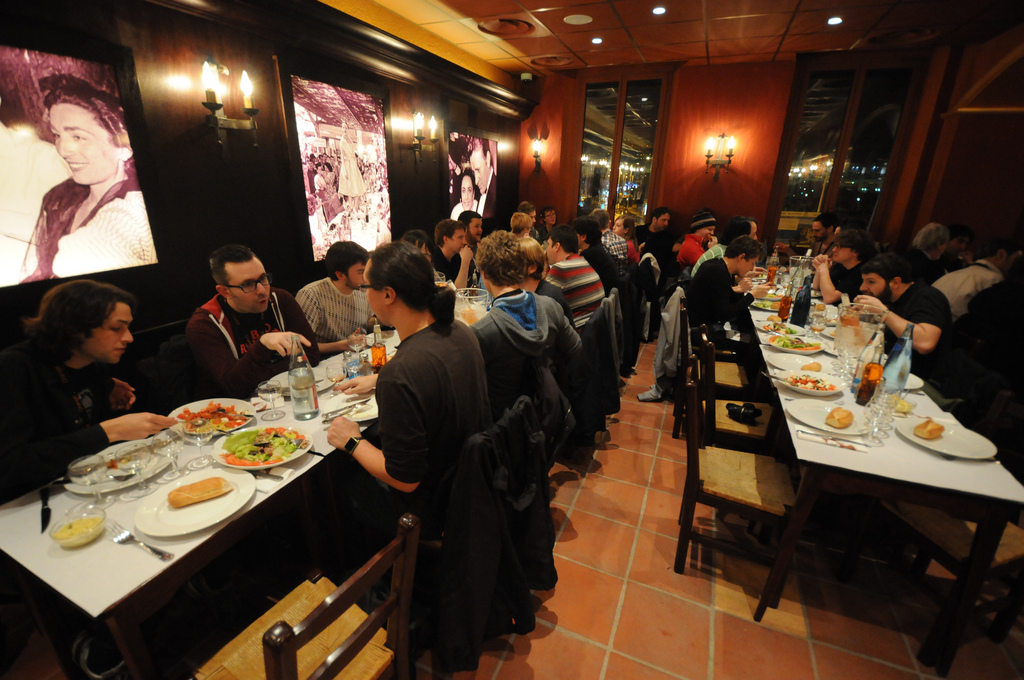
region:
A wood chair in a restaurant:
[185, 509, 417, 674]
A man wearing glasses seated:
[175, 246, 328, 393]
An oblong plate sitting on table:
[131, 461, 258, 538]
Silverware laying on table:
[98, 500, 172, 559]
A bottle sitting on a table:
[287, 330, 323, 422]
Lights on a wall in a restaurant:
[195, 47, 260, 146]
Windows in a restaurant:
[570, 74, 656, 237]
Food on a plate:
[224, 424, 302, 463]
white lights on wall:
[520, 108, 809, 222]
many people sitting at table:
[14, 228, 645, 573]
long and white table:
[0, 304, 456, 608]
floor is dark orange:
[611, 430, 716, 675]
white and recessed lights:
[579, 0, 845, 49]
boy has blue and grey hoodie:
[488, 287, 546, 377]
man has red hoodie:
[157, 263, 274, 403]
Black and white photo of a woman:
[0, 51, 171, 279]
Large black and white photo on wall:
[271, 63, 402, 269]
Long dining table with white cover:
[726, 241, 1017, 654]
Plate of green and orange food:
[206, 416, 323, 475]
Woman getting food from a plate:
[1, 271, 252, 440]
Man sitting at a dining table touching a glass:
[177, 234, 320, 402]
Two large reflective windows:
[557, 63, 672, 223]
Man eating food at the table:
[838, 247, 959, 375]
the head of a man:
[202, 250, 285, 317]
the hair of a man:
[212, 236, 247, 271]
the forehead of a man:
[230, 262, 266, 276]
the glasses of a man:
[230, 274, 272, 291]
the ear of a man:
[200, 281, 242, 300]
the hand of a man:
[250, 318, 312, 363]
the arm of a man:
[184, 328, 277, 382]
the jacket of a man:
[183, 299, 320, 367]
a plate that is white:
[133, 470, 244, 532]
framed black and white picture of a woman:
[0, 28, 174, 319]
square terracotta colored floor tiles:
[400, 331, 1021, 677]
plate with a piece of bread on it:
[129, 462, 259, 536]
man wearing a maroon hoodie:
[179, 234, 320, 399]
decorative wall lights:
[698, 127, 737, 182]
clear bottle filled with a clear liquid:
[288, 332, 317, 421]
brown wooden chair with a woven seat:
[190, 506, 422, 677]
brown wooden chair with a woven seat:
[673, 372, 803, 622]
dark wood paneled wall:
[2, 0, 540, 506]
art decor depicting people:
[0, 32, 513, 289]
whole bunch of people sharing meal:
[12, 195, 1022, 551]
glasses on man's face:
[215, 269, 273, 292]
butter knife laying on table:
[27, 473, 60, 535]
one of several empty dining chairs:
[176, 508, 442, 677]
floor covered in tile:
[446, 332, 1022, 675]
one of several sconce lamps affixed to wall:
[201, 51, 272, 160]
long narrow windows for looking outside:
[559, 47, 937, 244]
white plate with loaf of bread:
[133, 455, 254, 541]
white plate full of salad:
[209, 416, 312, 475]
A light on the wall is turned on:
[683, 115, 756, 192]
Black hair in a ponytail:
[352, 226, 466, 337]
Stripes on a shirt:
[528, 244, 614, 324]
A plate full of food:
[200, 413, 318, 477]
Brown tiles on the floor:
[465, 323, 1016, 669]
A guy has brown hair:
[10, 269, 141, 371]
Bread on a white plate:
[125, 453, 258, 549]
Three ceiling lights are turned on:
[576, 1, 849, 55]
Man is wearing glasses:
[197, 231, 277, 321]